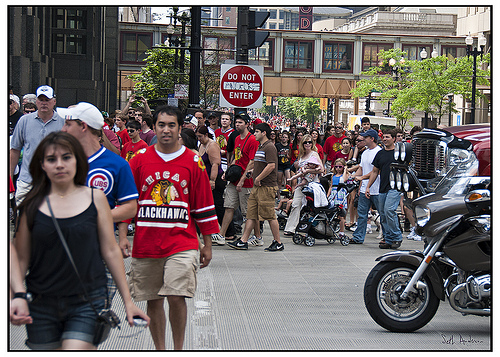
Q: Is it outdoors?
A: Yes, it is outdoors.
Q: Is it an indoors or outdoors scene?
A: It is outdoors.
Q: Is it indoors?
A: No, it is outdoors.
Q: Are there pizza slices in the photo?
A: No, there are no pizza slices.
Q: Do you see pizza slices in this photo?
A: No, there are no pizza slices.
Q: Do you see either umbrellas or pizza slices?
A: No, there are no pizza slices or umbrellas.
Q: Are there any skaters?
A: No, there are no skaters.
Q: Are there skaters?
A: No, there are no skaters.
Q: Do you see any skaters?
A: No, there are no skaters.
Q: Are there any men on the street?
A: Yes, there is a man on the street.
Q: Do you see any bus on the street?
A: No, there is a man on the street.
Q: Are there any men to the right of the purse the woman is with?
A: Yes, there is a man to the right of the purse.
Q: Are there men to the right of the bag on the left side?
A: Yes, there is a man to the right of the purse.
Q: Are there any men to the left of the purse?
A: No, the man is to the right of the purse.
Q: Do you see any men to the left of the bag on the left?
A: No, the man is to the right of the purse.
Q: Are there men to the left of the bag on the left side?
A: No, the man is to the right of the purse.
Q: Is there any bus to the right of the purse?
A: No, there is a man to the right of the purse.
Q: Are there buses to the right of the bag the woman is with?
A: No, there is a man to the right of the purse.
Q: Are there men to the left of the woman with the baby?
A: Yes, there is a man to the left of the woman.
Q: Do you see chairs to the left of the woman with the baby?
A: No, there is a man to the left of the woman.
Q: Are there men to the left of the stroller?
A: Yes, there is a man to the left of the stroller.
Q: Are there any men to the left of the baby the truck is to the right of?
A: Yes, there is a man to the left of the baby.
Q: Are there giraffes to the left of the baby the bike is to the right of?
A: No, there is a man to the left of the baby.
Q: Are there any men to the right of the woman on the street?
A: Yes, there is a man to the right of the woman.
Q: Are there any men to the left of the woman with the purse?
A: No, the man is to the right of the woman.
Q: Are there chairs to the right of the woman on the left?
A: No, there is a man to the right of the woman.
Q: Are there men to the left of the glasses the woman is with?
A: Yes, there is a man to the left of the glasses.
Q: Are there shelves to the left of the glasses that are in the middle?
A: No, there is a man to the left of the glasses.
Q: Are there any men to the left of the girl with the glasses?
A: Yes, there is a man to the left of the girl.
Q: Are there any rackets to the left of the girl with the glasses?
A: No, there is a man to the left of the girl.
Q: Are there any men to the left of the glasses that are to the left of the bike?
A: Yes, there is a man to the left of the glasses.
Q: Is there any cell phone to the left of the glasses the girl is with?
A: No, there is a man to the left of the glasses.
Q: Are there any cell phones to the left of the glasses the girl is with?
A: No, there is a man to the left of the glasses.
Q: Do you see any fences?
A: No, there are no fences.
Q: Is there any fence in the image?
A: No, there are no fences.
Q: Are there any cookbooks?
A: No, there are no cookbooks.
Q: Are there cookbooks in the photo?
A: No, there are no cookbooks.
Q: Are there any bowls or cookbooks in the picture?
A: No, there are no cookbooks or bowls.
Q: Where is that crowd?
A: The crowd is on the street.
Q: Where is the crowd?
A: The crowd is in the street.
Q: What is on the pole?
A: The sign is on the pole.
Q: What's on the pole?
A: The sign is on the pole.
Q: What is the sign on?
A: The sign is on the pole.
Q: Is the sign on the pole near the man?
A: Yes, the sign is on the pole.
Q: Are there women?
A: Yes, there is a woman.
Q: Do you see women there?
A: Yes, there is a woman.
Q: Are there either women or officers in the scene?
A: Yes, there is a woman.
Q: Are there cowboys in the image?
A: No, there are no cowboys.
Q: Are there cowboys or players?
A: No, there are no cowboys or players.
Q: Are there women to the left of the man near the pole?
A: Yes, there is a woman to the left of the man.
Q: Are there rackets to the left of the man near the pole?
A: No, there is a woman to the left of the man.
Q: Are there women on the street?
A: Yes, there is a woman on the street.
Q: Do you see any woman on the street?
A: Yes, there is a woman on the street.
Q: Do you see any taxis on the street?
A: No, there is a woman on the street.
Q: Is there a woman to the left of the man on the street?
A: Yes, there is a woman to the left of the man.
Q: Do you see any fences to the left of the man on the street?
A: No, there is a woman to the left of the man.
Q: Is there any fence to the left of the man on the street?
A: No, there is a woman to the left of the man.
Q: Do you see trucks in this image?
A: Yes, there is a truck.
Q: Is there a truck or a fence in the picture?
A: Yes, there is a truck.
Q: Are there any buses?
A: No, there are no buses.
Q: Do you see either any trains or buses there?
A: No, there are no buses or trains.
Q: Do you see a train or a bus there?
A: No, there are no buses or trains.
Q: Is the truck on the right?
A: Yes, the truck is on the right of the image.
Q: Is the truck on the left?
A: No, the truck is on the right of the image.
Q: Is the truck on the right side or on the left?
A: The truck is on the right of the image.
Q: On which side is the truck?
A: The truck is on the right of the image.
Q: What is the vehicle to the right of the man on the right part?
A: The vehicle is a truck.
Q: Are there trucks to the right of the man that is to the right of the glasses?
A: Yes, there is a truck to the right of the man.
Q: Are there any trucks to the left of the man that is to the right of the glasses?
A: No, the truck is to the right of the man.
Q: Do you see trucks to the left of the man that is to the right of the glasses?
A: No, the truck is to the right of the man.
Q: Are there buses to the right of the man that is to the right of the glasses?
A: No, there is a truck to the right of the man.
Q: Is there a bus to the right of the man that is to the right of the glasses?
A: No, there is a truck to the right of the man.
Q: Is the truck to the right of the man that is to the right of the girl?
A: Yes, the truck is to the right of the man.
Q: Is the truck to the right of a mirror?
A: No, the truck is to the right of the man.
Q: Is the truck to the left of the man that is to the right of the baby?
A: No, the truck is to the right of the man.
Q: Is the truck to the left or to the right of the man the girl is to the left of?
A: The truck is to the right of the man.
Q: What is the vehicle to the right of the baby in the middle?
A: The vehicle is a truck.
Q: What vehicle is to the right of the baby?
A: The vehicle is a truck.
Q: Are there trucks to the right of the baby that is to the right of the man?
A: Yes, there is a truck to the right of the baby.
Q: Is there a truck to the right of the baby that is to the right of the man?
A: Yes, there is a truck to the right of the baby.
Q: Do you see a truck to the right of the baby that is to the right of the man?
A: Yes, there is a truck to the right of the baby.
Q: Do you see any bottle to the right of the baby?
A: No, there is a truck to the right of the baby.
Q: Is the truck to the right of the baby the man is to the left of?
A: Yes, the truck is to the right of the baby.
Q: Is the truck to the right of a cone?
A: No, the truck is to the right of the baby.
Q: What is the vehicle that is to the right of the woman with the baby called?
A: The vehicle is a truck.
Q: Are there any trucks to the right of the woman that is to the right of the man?
A: Yes, there is a truck to the right of the woman.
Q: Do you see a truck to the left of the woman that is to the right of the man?
A: No, the truck is to the right of the woman.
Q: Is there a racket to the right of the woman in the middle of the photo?
A: No, there is a truck to the right of the woman.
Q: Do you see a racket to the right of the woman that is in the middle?
A: No, there is a truck to the right of the woman.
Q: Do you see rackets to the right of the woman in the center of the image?
A: No, there is a truck to the right of the woman.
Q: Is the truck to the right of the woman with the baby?
A: Yes, the truck is to the right of the woman.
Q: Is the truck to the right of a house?
A: No, the truck is to the right of the woman.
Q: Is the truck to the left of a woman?
A: No, the truck is to the right of a woman.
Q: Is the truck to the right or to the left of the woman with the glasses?
A: The truck is to the right of the woman.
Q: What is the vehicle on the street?
A: The vehicle is a truck.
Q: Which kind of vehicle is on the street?
A: The vehicle is a truck.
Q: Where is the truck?
A: The truck is on the street.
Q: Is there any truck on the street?
A: Yes, there is a truck on the street.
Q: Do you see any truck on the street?
A: Yes, there is a truck on the street.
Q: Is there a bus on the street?
A: No, there is a truck on the street.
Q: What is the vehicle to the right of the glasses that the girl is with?
A: The vehicle is a truck.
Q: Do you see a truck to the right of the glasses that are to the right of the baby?
A: Yes, there is a truck to the right of the glasses.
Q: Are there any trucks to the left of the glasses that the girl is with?
A: No, the truck is to the right of the glasses.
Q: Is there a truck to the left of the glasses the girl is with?
A: No, the truck is to the right of the glasses.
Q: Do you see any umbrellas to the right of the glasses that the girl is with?
A: No, there is a truck to the right of the glasses.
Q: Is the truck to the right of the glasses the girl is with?
A: Yes, the truck is to the right of the glasses.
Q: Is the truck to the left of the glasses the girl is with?
A: No, the truck is to the right of the glasses.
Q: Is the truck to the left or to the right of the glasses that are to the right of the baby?
A: The truck is to the right of the glasses.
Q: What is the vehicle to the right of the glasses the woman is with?
A: The vehicle is a truck.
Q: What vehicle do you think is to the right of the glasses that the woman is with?
A: The vehicle is a truck.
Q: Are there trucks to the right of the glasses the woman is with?
A: Yes, there is a truck to the right of the glasses.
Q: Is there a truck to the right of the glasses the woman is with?
A: Yes, there is a truck to the right of the glasses.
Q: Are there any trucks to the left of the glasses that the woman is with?
A: No, the truck is to the right of the glasses.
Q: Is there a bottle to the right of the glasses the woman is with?
A: No, there is a truck to the right of the glasses.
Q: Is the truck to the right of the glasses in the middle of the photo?
A: Yes, the truck is to the right of the glasses.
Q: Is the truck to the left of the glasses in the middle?
A: No, the truck is to the right of the glasses.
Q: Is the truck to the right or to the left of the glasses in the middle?
A: The truck is to the right of the glasses.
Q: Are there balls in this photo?
A: No, there are no balls.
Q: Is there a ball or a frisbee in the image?
A: No, there are no balls or frisbees.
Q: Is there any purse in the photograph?
A: Yes, there is a purse.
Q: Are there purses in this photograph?
A: Yes, there is a purse.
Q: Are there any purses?
A: Yes, there is a purse.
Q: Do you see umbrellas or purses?
A: Yes, there is a purse.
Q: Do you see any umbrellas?
A: No, there are no umbrellas.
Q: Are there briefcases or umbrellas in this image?
A: No, there are no umbrellas or briefcases.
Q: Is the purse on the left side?
A: Yes, the purse is on the left of the image.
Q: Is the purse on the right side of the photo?
A: No, the purse is on the left of the image.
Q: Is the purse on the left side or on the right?
A: The purse is on the left of the image.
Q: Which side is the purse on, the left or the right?
A: The purse is on the left of the image.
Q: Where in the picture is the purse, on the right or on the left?
A: The purse is on the left of the image.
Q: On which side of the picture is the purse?
A: The purse is on the left of the image.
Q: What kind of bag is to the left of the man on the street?
A: The bag is a purse.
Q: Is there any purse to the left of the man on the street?
A: Yes, there is a purse to the left of the man.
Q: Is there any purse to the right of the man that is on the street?
A: No, the purse is to the left of the man.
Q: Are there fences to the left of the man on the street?
A: No, there is a purse to the left of the man.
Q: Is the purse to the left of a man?
A: Yes, the purse is to the left of a man.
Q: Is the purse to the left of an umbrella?
A: No, the purse is to the left of a man.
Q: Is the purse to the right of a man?
A: No, the purse is to the left of a man.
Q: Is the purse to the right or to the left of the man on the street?
A: The purse is to the left of the man.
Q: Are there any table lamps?
A: No, there are no table lamps.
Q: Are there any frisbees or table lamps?
A: No, there are no table lamps or frisbees.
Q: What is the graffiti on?
A: The graffiti is on the sign.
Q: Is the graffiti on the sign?
A: Yes, the graffiti is on the sign.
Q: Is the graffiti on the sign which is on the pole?
A: Yes, the graffiti is on the sign.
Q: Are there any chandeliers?
A: No, there are no chandeliers.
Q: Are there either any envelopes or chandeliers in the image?
A: No, there are no chandeliers or envelopes.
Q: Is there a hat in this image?
A: Yes, there is a hat.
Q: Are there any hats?
A: Yes, there is a hat.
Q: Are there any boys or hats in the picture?
A: Yes, there is a hat.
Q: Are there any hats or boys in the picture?
A: Yes, there is a hat.